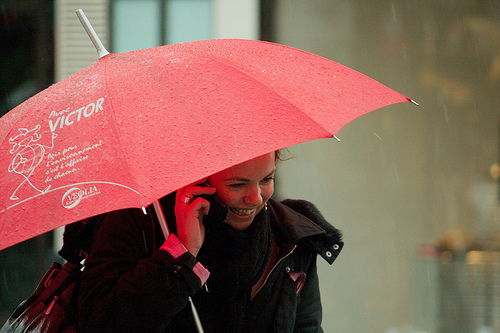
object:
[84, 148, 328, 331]
woman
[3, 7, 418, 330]
umbrella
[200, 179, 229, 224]
phone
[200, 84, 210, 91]
rain drop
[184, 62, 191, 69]
rain drop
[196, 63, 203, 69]
rain drop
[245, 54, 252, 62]
rain drop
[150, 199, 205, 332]
handle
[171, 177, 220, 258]
hand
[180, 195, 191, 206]
ring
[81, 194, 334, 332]
jacket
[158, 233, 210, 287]
cuff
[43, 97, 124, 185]
lettering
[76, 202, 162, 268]
shoulder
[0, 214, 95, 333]
handbag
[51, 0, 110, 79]
shutter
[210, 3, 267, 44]
shutter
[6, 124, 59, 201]
logo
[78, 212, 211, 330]
sleeve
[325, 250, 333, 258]
snap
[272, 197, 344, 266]
hood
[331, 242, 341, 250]
snap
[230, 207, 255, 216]
teeth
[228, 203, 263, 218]
mouth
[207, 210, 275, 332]
scarf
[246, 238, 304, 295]
zipper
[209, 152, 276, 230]
face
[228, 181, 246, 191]
eye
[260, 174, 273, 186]
eye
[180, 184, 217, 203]
finger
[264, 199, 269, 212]
earring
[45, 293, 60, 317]
zipper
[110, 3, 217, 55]
window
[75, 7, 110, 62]
top